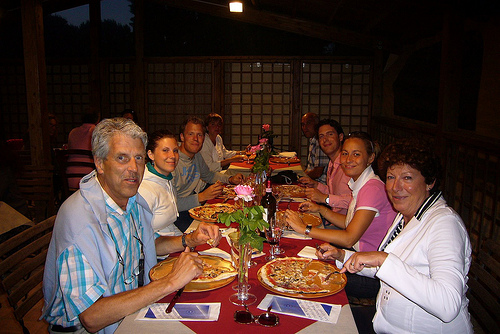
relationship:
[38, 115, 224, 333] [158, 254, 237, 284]
man eating a personal pizza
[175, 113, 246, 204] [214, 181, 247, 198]
man eating a personal pizza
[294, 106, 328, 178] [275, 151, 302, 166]
man eating a personal pizza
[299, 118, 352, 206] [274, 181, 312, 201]
man eating a personal pizza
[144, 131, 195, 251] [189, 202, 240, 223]
woman eating a personal pizza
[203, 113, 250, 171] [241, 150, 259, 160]
woman eating a personal pizza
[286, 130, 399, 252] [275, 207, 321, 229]
woman eating a personal pizza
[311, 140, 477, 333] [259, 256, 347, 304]
woman eating a personal pizza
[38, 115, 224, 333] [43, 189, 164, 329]
man wearing a checkered shirt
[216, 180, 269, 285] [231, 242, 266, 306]
flowers in a vase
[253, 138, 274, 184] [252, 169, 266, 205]
flowers in a vase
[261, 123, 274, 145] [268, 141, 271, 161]
flowers in a vase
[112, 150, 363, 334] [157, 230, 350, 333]
table with a red tablecloth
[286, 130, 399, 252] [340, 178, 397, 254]
woman wearing a pink shirt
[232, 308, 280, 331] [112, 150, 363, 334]
sunglasses are on table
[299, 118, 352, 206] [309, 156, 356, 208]
man in a pink shirt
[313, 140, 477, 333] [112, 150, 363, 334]
woman sitting together at table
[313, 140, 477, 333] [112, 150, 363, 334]
woman eating at table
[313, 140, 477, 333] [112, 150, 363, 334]
woman sitting down at table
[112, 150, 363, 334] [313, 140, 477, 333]
table with food and woman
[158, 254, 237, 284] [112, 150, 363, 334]
pizza on table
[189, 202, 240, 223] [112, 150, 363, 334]
pizza on table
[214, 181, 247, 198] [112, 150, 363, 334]
pizza on table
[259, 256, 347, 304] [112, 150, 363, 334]
pizza on table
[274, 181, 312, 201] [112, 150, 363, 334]
pizza on table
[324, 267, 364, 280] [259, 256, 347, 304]
fork in pizza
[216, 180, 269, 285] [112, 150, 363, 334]
flowers on table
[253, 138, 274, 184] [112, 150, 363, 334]
flowers on table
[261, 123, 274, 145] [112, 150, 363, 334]
flowers on table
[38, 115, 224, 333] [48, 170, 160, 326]
man wearing a sweater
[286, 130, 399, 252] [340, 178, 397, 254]
woman in a pink shirt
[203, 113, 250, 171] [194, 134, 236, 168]
woman wearing a white shirt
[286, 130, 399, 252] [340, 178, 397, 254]
woman wearing a shirt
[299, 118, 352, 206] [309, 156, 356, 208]
man wearing a shirt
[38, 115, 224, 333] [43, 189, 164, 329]
man wearing a shirt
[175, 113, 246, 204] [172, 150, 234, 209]
man in a gray shirt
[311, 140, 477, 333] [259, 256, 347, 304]
woman cutting her pizza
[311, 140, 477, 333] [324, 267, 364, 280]
woman holding her fork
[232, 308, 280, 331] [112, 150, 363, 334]
sunglasses sitting on table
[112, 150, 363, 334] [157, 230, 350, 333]
table covered by tablecloth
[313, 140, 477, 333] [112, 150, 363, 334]
woman sitting at table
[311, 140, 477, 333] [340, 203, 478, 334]
woman wearing white jacket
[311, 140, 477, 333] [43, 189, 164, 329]
woman in black and white shirt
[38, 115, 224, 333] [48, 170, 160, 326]
man wearing sweater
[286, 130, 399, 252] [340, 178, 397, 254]
woman wearing pink shirt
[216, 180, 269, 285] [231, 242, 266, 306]
flowers in vase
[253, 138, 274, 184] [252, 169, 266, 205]
flowers in vase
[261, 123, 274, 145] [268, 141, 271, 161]
flowers in vase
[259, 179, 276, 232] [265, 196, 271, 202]
bottle color brown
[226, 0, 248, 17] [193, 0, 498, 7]
light hanging from ceiling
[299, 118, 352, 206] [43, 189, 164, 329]
man in a shirt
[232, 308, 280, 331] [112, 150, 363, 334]
sunglasses on table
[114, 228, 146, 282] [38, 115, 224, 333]
glasses are hanging on man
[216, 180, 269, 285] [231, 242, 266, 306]
flowers in a vase on vase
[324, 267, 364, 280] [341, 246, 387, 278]
fork in womans hand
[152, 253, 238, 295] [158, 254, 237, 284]
plate with a pizza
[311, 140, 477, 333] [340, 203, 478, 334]
woman wearing a white jacket